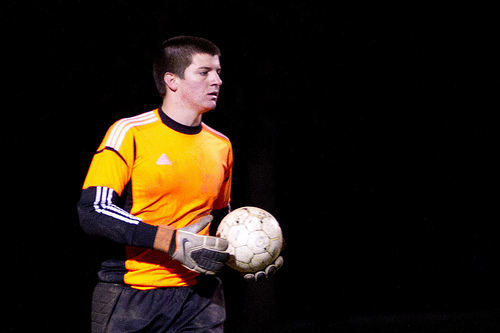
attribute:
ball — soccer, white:
[215, 206, 284, 270]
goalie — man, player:
[74, 31, 285, 331]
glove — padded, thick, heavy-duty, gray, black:
[166, 212, 234, 277]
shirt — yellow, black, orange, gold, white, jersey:
[78, 110, 231, 285]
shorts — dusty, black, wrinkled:
[89, 273, 229, 332]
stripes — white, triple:
[107, 109, 155, 149]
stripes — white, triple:
[94, 184, 141, 225]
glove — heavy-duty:
[240, 256, 284, 279]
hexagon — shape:
[227, 223, 250, 248]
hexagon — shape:
[261, 213, 280, 239]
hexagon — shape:
[234, 244, 253, 263]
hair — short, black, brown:
[152, 32, 220, 96]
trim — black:
[156, 105, 207, 134]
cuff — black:
[135, 217, 160, 249]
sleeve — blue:
[78, 186, 158, 247]